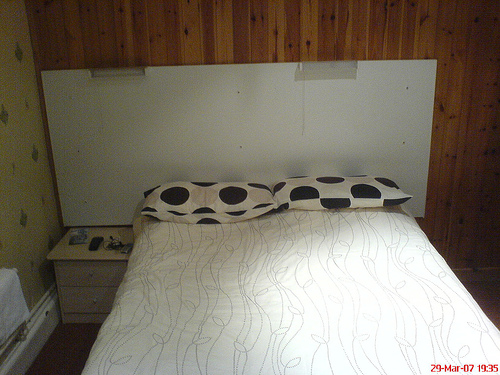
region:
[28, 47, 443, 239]
white rectangle headboard on wall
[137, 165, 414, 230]
two pillows with circle designs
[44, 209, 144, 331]
light tan night stand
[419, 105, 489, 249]
wood panel wall of bedroom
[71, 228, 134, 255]
various items on side of bed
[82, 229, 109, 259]
cell phone on nightstand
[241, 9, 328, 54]
wood knots in panel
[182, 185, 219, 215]
light tan circle on pillow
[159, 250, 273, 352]
curvy lines on bed covering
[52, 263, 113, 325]
two drawers on night stand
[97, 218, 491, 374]
Large bed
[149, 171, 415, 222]
Two black polka dot pillows.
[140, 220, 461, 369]
White bedspread with gray pattern.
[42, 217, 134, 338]
Nightstand with two drawers.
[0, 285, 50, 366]
White heat register on the wall.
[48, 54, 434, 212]
A white headboard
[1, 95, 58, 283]
Old wallpaper with a design.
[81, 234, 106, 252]
Cell phone on the night stand.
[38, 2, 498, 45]
Old wood paneling on the wall.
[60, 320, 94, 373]
Brown carpeting.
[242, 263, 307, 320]
part of a sheet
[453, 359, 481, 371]
part of a date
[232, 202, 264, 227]
edge of a pillow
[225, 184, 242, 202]
black part of a pillow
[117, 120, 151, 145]
part of a wall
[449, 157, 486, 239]
part of a wooden wall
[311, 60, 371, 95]
part of a shade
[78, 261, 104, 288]
part of a handle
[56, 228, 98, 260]
surface of a cupboard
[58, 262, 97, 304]
part of a cupboard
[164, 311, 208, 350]
black line on the sheet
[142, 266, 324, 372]
white sheet with black curly lines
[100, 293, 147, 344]
edge of double bed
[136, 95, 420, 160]
large white back board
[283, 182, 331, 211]
black circles on pillow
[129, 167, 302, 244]
white pillow on bed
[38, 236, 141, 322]
brown table beside bed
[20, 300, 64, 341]
white edge on flooer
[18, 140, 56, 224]
small symbols on the wall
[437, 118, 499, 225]
brown wooden wall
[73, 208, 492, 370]
thin black squiggly lines on the sheet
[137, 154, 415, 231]
black polka dots on pillows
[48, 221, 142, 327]
small night stand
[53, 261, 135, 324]
two drawers on the night stand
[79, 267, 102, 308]
two small silver knobs on the drawers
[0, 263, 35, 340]
a white towel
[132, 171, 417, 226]
beige polka dots on pillows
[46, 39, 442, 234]
white back board behind the bed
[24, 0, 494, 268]
brown wood panel wall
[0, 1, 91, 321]
leaves on wallpaper